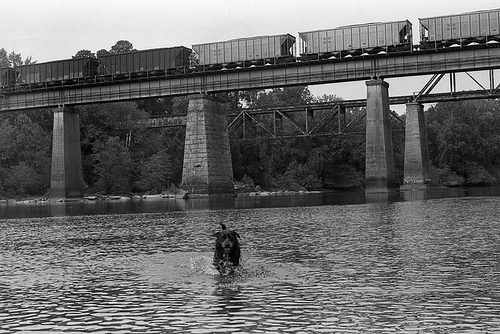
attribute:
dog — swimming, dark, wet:
[208, 219, 250, 280]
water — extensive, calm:
[3, 185, 498, 331]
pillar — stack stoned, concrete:
[179, 91, 241, 199]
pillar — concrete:
[363, 77, 398, 196]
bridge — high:
[1, 39, 499, 115]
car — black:
[91, 42, 195, 82]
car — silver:
[417, 6, 499, 51]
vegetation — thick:
[1, 36, 499, 190]